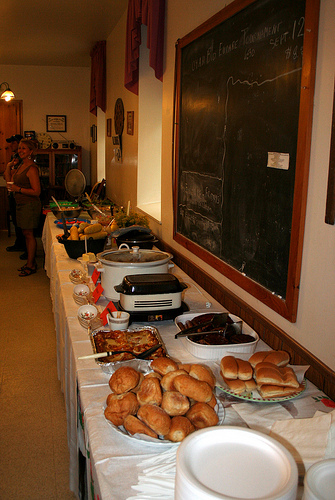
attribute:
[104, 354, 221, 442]
rolls — hot, piled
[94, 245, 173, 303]
crock pot — brown, tan, white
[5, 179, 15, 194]
cup — small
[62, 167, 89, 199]
fan — white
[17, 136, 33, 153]
hair — blonde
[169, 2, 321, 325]
blackboard — framed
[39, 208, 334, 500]
cloth — white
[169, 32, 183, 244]
edge — wooden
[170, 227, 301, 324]
edge — wooden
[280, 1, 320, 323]
edge — wooden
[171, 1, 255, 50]
edge — wooden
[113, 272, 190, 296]
lid — black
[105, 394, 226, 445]
dish — white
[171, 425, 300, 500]
dishes — stacked, white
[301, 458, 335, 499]
dishes — stacked, white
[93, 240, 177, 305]
pot — white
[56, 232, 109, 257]
bowl — black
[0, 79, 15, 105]
lamp — on left of room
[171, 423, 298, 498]
plates — stacked, white, paper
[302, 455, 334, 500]
plates — stacked, white, paper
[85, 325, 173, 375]
tray — metal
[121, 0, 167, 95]
curtains — red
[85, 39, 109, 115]
curtains — red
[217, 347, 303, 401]
rolls — smaller, piled